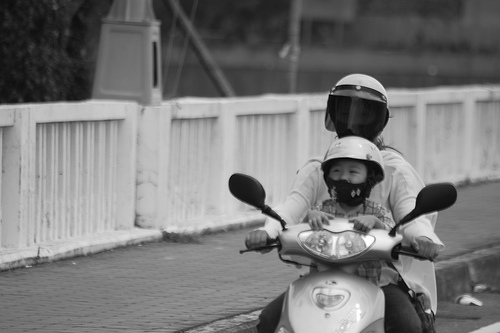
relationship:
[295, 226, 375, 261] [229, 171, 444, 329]
headlight on scooter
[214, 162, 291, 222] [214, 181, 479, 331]
mirror of scooter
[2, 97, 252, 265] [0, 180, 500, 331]
bridge railing and sidewalk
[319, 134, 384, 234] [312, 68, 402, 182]
boy wearing helmet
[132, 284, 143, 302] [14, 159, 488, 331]
brick on a sidewalk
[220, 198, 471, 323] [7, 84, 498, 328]
scooter going across bridge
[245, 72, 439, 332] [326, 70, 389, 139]
mother wearing full helmet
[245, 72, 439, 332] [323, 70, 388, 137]
mother wearing helmet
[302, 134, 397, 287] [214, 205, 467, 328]
boy on scooter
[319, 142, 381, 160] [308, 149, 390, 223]
helmet on child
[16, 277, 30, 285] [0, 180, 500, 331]
brick on sidewalk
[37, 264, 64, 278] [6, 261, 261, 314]
brick on sidewalk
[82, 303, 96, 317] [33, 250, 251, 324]
brick on sidewalk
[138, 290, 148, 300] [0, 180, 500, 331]
brick on sidewalk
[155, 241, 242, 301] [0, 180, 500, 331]
brick on sidewalk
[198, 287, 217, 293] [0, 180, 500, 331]
brick on sidewalk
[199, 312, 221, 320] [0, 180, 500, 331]
brick on sidewalk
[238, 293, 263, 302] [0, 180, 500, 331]
brick on sidewalk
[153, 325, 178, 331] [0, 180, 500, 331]
brick on sidewalk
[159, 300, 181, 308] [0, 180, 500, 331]
brick on sidewalk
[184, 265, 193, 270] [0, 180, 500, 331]
brick on sidewalk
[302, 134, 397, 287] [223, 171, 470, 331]
boy on scooter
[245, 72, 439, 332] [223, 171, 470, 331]
mother on scooter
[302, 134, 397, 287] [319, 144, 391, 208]
boy wearing helmet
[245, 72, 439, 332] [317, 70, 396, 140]
mother wearing helmet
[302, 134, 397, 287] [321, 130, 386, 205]
boy wearing helmet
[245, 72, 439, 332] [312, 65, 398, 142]
mother wearing helmet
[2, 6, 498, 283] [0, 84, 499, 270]
bridge with bridge railing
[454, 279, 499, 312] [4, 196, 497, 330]
trash on ground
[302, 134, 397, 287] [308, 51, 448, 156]
boy wearing helmet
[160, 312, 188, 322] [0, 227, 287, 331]
brick on sidewalk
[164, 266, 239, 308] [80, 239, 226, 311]
brick on sidewalk